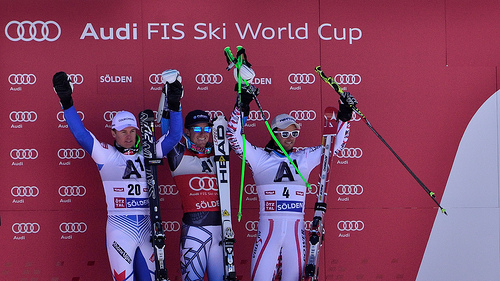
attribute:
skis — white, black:
[135, 149, 187, 269]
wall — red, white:
[0, 2, 498, 277]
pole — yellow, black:
[306, 60, 464, 222]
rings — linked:
[2, 144, 44, 166]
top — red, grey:
[168, 148, 223, 224]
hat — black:
[105, 109, 141, 135]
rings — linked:
[336, 180, 370, 195]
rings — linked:
[338, 214, 366, 236]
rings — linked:
[8, 180, 43, 202]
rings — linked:
[6, 72, 35, 83]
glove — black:
[50, 67, 75, 111]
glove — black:
[335, 89, 357, 120]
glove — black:
[233, 84, 256, 116]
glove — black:
[161, 79, 185, 110]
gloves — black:
[49, 72, 80, 112]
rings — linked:
[322, 62, 383, 97]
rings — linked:
[58, 185, 85, 197]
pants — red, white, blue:
[94, 213, 164, 279]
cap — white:
[109, 110, 138, 132]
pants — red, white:
[249, 212, 309, 279]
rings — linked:
[8, 109, 43, 133]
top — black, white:
[224, 74, 345, 279]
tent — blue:
[492, 73, 499, 101]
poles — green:
[196, 36, 337, 272]